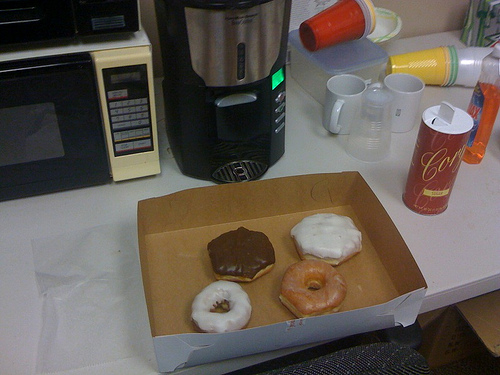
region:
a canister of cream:
[381, 88, 474, 218]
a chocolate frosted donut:
[198, 210, 283, 287]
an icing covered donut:
[280, 204, 376, 269]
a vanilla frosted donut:
[180, 272, 260, 341]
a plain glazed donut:
[276, 256, 355, 309]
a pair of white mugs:
[317, 73, 434, 136]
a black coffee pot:
[145, 4, 316, 201]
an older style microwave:
[5, 5, 172, 202]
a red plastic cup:
[303, 7, 385, 59]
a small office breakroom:
[3, 5, 475, 367]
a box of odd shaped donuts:
[124, 168, 431, 362]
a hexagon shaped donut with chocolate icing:
[206, 220, 278, 282]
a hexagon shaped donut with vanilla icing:
[288, 211, 365, 264]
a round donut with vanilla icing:
[186, 278, 251, 330]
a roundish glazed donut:
[270, 257, 348, 319]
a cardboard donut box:
[131, 189, 208, 281]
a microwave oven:
[0, 35, 162, 197]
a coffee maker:
[155, 2, 289, 177]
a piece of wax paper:
[27, 220, 137, 371]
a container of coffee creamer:
[403, 102, 474, 224]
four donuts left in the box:
[113, 175, 432, 344]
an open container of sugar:
[406, 90, 472, 223]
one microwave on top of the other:
[0, 4, 172, 202]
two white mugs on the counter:
[329, 69, 426, 151]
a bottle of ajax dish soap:
[461, 34, 494, 179]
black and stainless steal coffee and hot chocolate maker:
[156, 4, 315, 178]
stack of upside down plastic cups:
[333, 68, 398, 166]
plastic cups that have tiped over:
[381, 29, 498, 91]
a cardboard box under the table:
[423, 290, 498, 369]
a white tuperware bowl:
[291, 21, 401, 108]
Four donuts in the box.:
[172, 194, 369, 340]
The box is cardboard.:
[120, 162, 430, 348]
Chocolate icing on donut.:
[202, 222, 276, 281]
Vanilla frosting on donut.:
[286, 205, 361, 264]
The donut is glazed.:
[279, 256, 344, 317]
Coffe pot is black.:
[155, 2, 293, 184]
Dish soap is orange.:
[463, 37, 498, 166]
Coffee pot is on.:
[257, 61, 291, 93]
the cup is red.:
[294, 2, 371, 50]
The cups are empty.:
[314, 63, 426, 144]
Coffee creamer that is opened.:
[403, 99, 473, 214]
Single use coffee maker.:
[155, 11, 294, 183]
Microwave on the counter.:
[2, 31, 164, 200]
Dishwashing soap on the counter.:
[461, 53, 498, 166]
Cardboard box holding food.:
[136, 166, 427, 368]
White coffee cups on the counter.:
[320, 73, 425, 135]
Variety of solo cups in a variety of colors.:
[300, 1, 498, 164]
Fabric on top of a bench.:
[256, 328, 433, 373]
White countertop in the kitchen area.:
[6, 29, 498, 371]